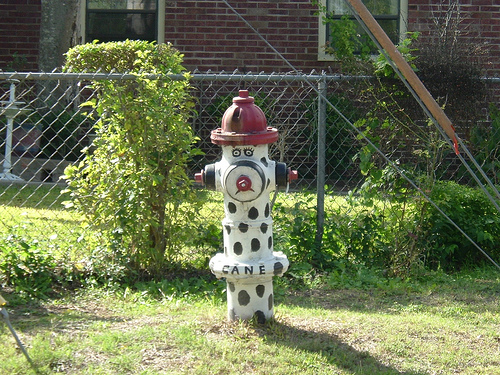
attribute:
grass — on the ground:
[15, 327, 187, 371]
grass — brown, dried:
[11, 280, 484, 372]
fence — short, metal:
[3, 64, 479, 288]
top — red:
[212, 91, 270, 148]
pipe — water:
[176, 84, 311, 319]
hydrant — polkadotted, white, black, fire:
[187, 77, 298, 329]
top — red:
[199, 84, 282, 146]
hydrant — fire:
[195, 79, 294, 336]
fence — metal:
[5, 55, 70, 235]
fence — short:
[9, 47, 108, 220]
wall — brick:
[188, 25, 248, 56]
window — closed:
[79, 0, 168, 49]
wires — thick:
[406, 70, 497, 266]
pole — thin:
[308, 145, 334, 275]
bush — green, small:
[49, 30, 207, 291]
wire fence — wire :
[278, 99, 318, 164]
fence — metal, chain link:
[0, 69, 498, 279]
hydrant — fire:
[185, 85, 312, 336]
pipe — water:
[191, 87, 311, 332]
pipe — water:
[178, 85, 299, 345]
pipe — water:
[188, 84, 302, 332]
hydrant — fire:
[184, 84, 328, 340]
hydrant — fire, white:
[196, 86, 304, 345]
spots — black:
[221, 204, 278, 326]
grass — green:
[10, 273, 499, 373]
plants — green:
[280, 196, 420, 290]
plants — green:
[0, 229, 78, 320]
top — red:
[210, 83, 280, 149]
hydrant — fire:
[200, 85, 310, 333]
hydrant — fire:
[199, 87, 298, 332]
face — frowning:
[223, 143, 265, 214]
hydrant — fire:
[192, 88, 305, 331]